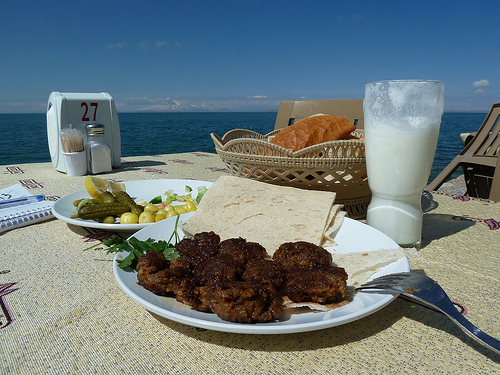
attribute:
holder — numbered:
[42, 88, 122, 175]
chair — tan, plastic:
[424, 101, 497, 203]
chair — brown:
[441, 101, 497, 208]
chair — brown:
[266, 94, 365, 131]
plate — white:
[79, 167, 454, 335]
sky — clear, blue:
[0, 0, 497, 111]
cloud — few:
[473, 78, 490, 85]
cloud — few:
[1, 92, 498, 111]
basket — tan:
[247, 112, 404, 199]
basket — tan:
[188, 105, 425, 225]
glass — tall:
[361, 74, 446, 252]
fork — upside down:
[353, 270, 498, 358]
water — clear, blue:
[0, 0, 498, 57]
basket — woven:
[208, 104, 365, 191]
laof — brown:
[245, 110, 360, 155]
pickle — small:
[115, 190, 142, 216]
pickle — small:
[78, 201, 130, 218]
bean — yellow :
[120, 212, 137, 224]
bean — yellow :
[138, 209, 155, 222]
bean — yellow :
[143, 202, 159, 211]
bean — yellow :
[166, 210, 178, 217]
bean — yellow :
[164, 203, 174, 211]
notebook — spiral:
[2, 180, 53, 237]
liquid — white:
[369, 114, 448, 131]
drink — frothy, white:
[366, 116, 438, 244]